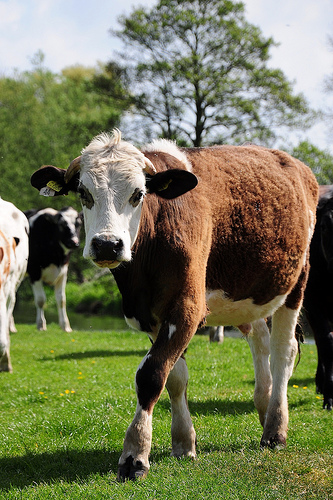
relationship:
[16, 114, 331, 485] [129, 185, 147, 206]
cow has eye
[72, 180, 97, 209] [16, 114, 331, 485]
eye on cow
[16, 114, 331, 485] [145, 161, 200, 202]
cow has ear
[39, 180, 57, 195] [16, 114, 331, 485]
tag on cow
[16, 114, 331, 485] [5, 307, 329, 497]
cow in a field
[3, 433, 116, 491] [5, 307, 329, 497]
shadow on ground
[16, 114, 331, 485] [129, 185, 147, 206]
cow on eye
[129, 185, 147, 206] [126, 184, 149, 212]
eye has brown ring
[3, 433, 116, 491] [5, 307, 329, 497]
shadow on grass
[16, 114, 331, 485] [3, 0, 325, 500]
animal facing forward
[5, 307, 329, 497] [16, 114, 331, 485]
grass under animals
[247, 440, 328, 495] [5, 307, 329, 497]
dandelions in field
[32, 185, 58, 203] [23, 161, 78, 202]
tag on air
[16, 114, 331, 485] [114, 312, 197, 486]
cow has leg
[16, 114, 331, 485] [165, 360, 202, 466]
cow has leg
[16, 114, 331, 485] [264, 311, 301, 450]
cow has leg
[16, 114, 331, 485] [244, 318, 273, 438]
cow has leg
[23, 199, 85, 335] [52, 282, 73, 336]
cow has leg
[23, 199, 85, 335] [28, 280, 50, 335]
cow has leg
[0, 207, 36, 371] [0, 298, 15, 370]
cow has leg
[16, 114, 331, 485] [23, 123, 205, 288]
cow has head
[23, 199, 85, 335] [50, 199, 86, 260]
cow has head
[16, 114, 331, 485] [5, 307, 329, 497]
cow in pasture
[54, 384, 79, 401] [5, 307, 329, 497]
flower in field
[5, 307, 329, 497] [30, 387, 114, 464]
grass on ground